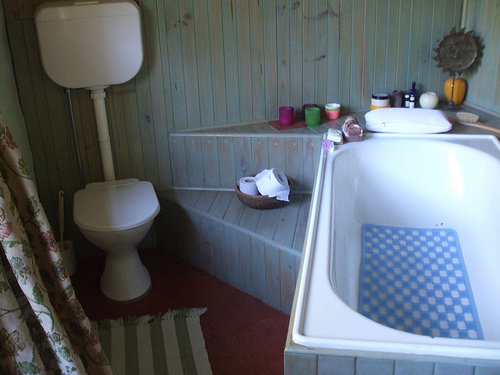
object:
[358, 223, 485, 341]
bath mat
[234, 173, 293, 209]
basket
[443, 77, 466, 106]
vase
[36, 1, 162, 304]
toilet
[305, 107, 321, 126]
cup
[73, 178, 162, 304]
toilet bowl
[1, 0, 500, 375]
bathroom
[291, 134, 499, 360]
tube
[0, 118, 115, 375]
curtain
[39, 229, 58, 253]
flower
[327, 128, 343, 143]
soap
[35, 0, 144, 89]
basin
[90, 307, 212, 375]
rug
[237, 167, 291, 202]
rolls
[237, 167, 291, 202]
toilet paper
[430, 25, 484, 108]
decorative sub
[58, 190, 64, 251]
toilet brush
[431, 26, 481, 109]
brush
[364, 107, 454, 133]
pillow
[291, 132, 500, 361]
bathtub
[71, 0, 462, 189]
wall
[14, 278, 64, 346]
part